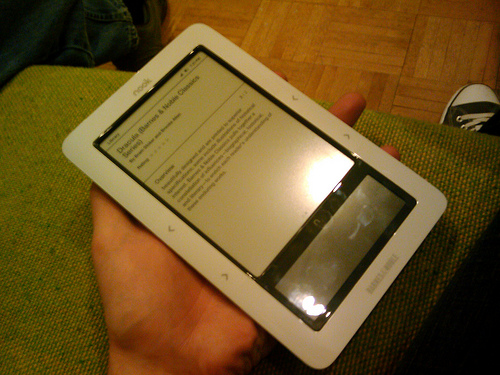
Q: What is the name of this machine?
A: Nook.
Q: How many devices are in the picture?
A: One.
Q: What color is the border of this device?
A: Silver.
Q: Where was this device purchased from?
A: Barnes & noble.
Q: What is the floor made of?
A: Wood.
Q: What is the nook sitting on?
A: Hand.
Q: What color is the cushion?
A: Green.